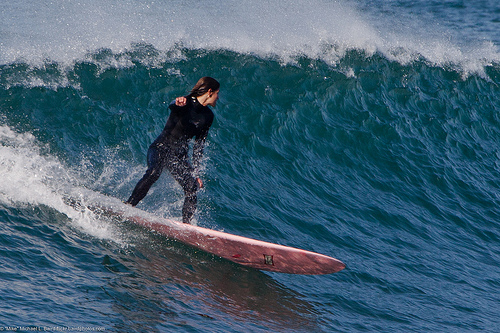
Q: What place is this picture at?
A: It is at the ocean.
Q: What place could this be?
A: It is an ocean.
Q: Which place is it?
A: It is an ocean.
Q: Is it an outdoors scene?
A: Yes, it is outdoors.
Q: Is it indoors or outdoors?
A: It is outdoors.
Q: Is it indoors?
A: No, it is outdoors.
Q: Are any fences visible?
A: No, there are no fences.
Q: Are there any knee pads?
A: No, there are no knee pads.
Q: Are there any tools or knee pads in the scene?
A: No, there are no knee pads or tools.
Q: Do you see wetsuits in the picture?
A: Yes, there is a wetsuit.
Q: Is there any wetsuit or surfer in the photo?
A: Yes, there is a wetsuit.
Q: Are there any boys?
A: No, there are no boys.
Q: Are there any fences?
A: No, there are no fences.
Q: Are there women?
A: Yes, there is a woman.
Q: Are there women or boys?
A: Yes, there is a woman.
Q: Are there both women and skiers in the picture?
A: No, there is a woman but no skiers.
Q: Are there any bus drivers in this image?
A: No, there are no bus drivers.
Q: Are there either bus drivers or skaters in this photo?
A: No, there are no bus drivers or skaters.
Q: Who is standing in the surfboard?
A: The woman is standing in the surfboard.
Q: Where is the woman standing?
A: The woman is standing in the surfboard.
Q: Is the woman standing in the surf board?
A: Yes, the woman is standing in the surf board.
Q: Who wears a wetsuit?
A: The woman wears a wetsuit.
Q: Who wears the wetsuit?
A: The woman wears a wetsuit.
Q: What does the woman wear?
A: The woman wears a wetsuit.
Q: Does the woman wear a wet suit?
A: Yes, the woman wears a wet suit.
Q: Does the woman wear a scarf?
A: No, the woman wears a wet suit.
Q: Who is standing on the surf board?
A: The woman is standing on the surf board.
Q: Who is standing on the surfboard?
A: The woman is standing on the surf board.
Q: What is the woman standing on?
A: The woman is standing on the surf board.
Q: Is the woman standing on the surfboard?
A: Yes, the woman is standing on the surfboard.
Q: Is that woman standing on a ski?
A: No, the woman is standing on the surfboard.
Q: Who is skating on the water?
A: The woman is skating on the water.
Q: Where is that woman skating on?
A: The woman is skating on the water.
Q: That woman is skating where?
A: The woman is skating on the water.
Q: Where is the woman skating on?
A: The woman is skating on the water.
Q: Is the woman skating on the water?
A: Yes, the woman is skating on the water.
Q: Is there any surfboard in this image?
A: Yes, there is a surfboard.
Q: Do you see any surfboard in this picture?
A: Yes, there is a surfboard.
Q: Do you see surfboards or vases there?
A: Yes, there is a surfboard.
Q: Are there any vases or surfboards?
A: Yes, there is a surfboard.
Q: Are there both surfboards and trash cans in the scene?
A: No, there is a surfboard but no trash cans.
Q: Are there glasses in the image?
A: No, there are no glasses.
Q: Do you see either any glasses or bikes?
A: No, there are no glasses or bikes.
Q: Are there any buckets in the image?
A: No, there are no buckets.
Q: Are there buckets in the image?
A: No, there are no buckets.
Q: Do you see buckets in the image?
A: No, there are no buckets.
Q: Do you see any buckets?
A: No, there are no buckets.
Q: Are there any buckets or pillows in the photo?
A: No, there are no buckets or pillows.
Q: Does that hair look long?
A: Yes, the hair is long.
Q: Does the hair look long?
A: Yes, the hair is long.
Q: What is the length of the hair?
A: The hair is long.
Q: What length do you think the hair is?
A: The hair is long.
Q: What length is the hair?
A: The hair is long.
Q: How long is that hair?
A: The hair is long.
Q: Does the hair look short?
A: No, the hair is long.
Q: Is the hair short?
A: No, the hair is long.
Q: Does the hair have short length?
A: No, the hair is long.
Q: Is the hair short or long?
A: The hair is long.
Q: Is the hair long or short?
A: The hair is long.